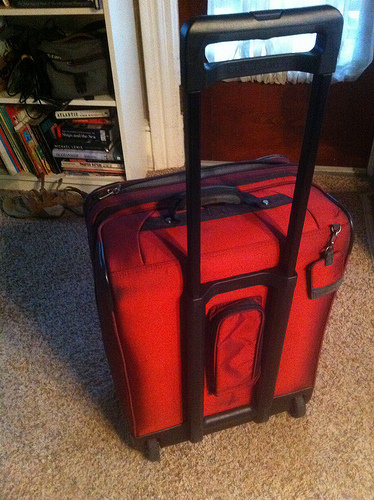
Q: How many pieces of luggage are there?
A: One.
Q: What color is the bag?
A: Red.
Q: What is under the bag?
A: Carpet.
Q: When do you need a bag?
A: When you are traveling.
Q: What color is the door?
A: Brown.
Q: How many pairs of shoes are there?
A: One.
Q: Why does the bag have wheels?
A: To pull it easily.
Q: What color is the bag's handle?
A: Black.